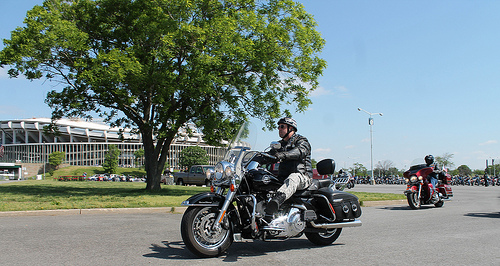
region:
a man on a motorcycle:
[154, 116, 373, 260]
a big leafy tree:
[8, 4, 318, 192]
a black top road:
[370, 210, 487, 255]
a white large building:
[5, 109, 153, 167]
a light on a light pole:
[366, 105, 376, 187]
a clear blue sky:
[336, 1, 488, 106]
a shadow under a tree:
[3, 182, 195, 201]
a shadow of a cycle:
[147, 236, 203, 260]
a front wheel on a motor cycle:
[168, 193, 241, 255]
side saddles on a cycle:
[315, 195, 374, 231]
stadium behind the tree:
[22, 107, 150, 170]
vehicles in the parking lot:
[89, 159, 144, 189]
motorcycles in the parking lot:
[457, 164, 482, 183]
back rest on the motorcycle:
[315, 150, 345, 184]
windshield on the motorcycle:
[243, 115, 256, 168]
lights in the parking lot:
[361, 101, 387, 165]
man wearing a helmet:
[265, 114, 296, 132]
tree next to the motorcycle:
[79, 15, 223, 192]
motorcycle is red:
[393, 159, 453, 209]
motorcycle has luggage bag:
[316, 194, 360, 231]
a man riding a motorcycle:
[161, 83, 383, 265]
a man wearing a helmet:
[258, 112, 315, 141]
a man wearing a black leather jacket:
[261, 119, 318, 171]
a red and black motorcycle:
[385, 151, 470, 216]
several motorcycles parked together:
[351, 163, 494, 190]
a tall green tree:
[51, 39, 214, 191]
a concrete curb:
[16, 200, 159, 217]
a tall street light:
[352, 102, 388, 186]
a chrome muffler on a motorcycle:
[281, 201, 372, 241]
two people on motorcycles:
[133, 112, 458, 255]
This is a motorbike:
[399, 148, 461, 213]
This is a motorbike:
[163, 115, 370, 258]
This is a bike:
[169, 111, 375, 257]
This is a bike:
[390, 145, 465, 214]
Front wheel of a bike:
[168, 185, 245, 257]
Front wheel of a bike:
[401, 179, 426, 212]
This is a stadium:
[0, 114, 265, 182]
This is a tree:
[4, 0, 347, 197]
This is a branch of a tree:
[135, 18, 163, 127]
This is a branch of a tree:
[2, 31, 151, 137]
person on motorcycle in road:
[180, 128, 363, 248]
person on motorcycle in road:
[403, 152, 471, 227]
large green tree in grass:
[12, 10, 268, 178]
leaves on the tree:
[50, 111, 72, 131]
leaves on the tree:
[203, 75, 230, 102]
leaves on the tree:
[236, 50, 280, 90]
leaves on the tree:
[130, 39, 162, 71]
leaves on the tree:
[188, 145, 200, 164]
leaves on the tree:
[28, 32, 64, 61]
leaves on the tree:
[83, 18, 105, 34]